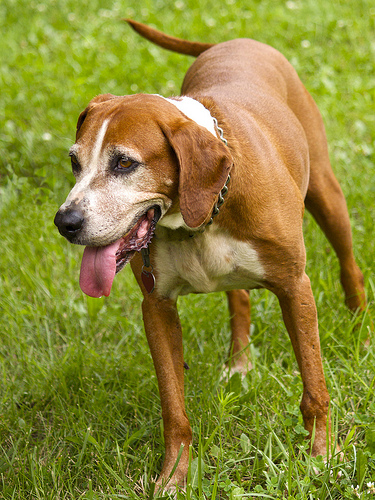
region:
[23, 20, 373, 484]
a dog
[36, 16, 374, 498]
a dog in the grass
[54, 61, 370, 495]
the dog is a redish-brown in color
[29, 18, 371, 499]
the dog is brown and white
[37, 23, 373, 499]
the dog has a pink tongue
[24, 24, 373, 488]
the dog is walking in the grass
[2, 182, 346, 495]
the grass is green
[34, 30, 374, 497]
the dog is wearing a metal collar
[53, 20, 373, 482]
the dog is panting and it's tongue hangs out of it's mouth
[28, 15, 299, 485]
a red heart hangs from the dog's collar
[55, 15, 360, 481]
the dog is standing on the grass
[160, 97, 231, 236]
the dog has a collar on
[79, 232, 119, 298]
the dog has his tongue sticking out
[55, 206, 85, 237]
the dog has a black nose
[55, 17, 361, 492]
the dog is brown in color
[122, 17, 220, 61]
the dog is waggling his tail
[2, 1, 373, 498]
the grass is green in color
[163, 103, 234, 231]
the dog's collar is a chain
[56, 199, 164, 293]
the dog is panting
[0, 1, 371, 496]
the photo was taken outdoors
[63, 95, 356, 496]
dog standing in the grass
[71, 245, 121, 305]
dog's tongue is pink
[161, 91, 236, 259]
dog is wearing a collar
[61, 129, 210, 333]
dog's tongue is hanging out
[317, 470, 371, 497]
flowers in the grass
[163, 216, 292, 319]
the dog is white and brown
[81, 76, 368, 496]
dog is standing in the grass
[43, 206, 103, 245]
the dog's nose is black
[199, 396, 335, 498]
clovers in the grass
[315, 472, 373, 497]
flowers are white and yellow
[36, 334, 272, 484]
grass blades are green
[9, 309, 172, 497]
grass blades are green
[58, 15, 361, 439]
brown and white dog on grass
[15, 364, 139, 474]
green grass in field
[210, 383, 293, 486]
green grass in field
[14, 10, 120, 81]
green grass in field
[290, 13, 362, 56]
green grass in field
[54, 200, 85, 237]
black nose of brown dog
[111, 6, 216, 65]
brown tail of brown dog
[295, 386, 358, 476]
brown left front foot of brown dog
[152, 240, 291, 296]
white chest of brown dog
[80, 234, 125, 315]
pink tongue of brown dog